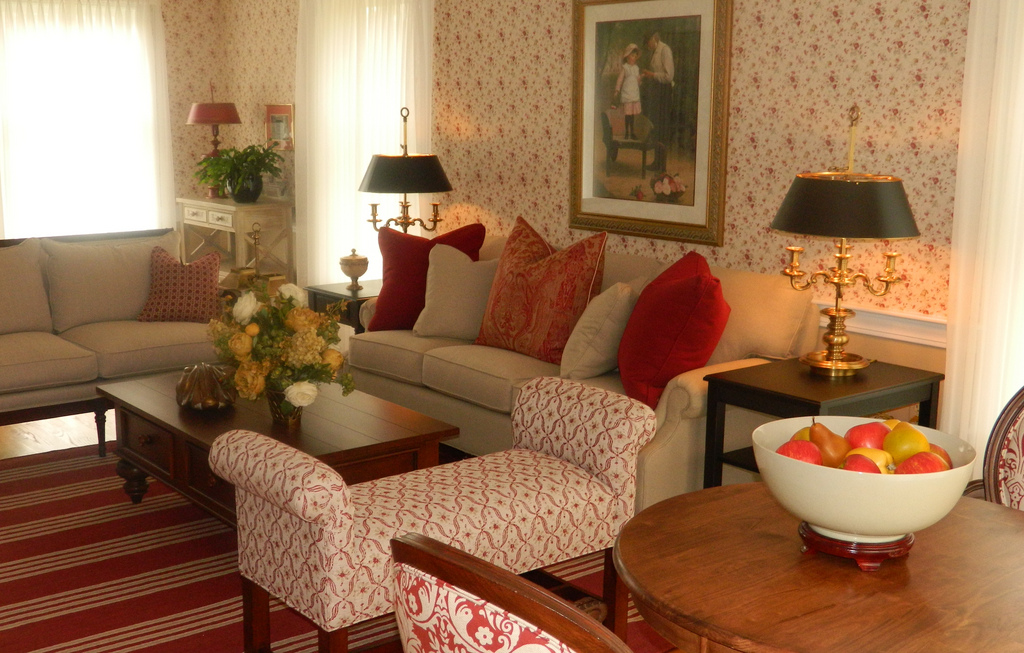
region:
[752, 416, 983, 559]
fruits inside a bowl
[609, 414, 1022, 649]
bowl on top of table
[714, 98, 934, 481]
lamp on top of table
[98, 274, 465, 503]
flower arrangement on top of table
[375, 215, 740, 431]
red and beige pillows on sofa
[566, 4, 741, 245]
picture hanging on wall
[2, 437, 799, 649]
striped rug on floor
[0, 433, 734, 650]
rug is white and red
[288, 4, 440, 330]
window has white curtain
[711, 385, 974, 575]
a view of fruits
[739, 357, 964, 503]
a group of fruits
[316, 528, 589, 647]
a view of chair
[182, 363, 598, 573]
a view of sofa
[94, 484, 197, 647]
a view of floor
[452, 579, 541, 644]
a design in the chair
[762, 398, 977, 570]
a white bowl of fruit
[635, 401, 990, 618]
a bowl of fruit on a table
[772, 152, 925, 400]
a lamp on a square table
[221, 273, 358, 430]
a vase of flowers on a table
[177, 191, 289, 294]
a small white table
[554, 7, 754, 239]
a framed picture on a wall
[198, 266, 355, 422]
Colorful bouquet on shiny wooden table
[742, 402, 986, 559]
Wide bowl holding fruits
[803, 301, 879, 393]
Gold plated lamp holder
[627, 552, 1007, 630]
Shiny circular dinner table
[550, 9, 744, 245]
Gold framed wall painting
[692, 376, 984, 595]
bowl of food on table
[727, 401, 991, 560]
white bowl of fruit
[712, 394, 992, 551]
white bowl of fruit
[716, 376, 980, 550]
white bowl of fruit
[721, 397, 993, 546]
white bowl of fruit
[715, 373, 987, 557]
white bowl of fruit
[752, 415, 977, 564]
large white bowl of fruit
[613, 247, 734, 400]
large dark red throw pillow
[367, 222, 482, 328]
large dark red throw pillow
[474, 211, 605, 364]
large dark red and gold throw pillow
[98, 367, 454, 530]
short dark wood coffee table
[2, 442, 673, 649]
striped area rug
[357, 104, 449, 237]
gold lamp with a black lamp shade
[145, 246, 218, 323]
small red and white throw pillow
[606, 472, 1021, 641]
round dining room table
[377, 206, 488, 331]
red and tan pillows on sofa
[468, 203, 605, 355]
red and tan pillows on sofa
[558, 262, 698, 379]
red and tan pillows on sofa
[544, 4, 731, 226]
painting hanging on wall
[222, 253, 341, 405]
flowers in vase on table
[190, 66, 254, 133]
red colored lamp shade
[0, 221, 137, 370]
tan colored sofa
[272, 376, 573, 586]
red and white settee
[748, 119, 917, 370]
light turned on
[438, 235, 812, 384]
orange and white cushions